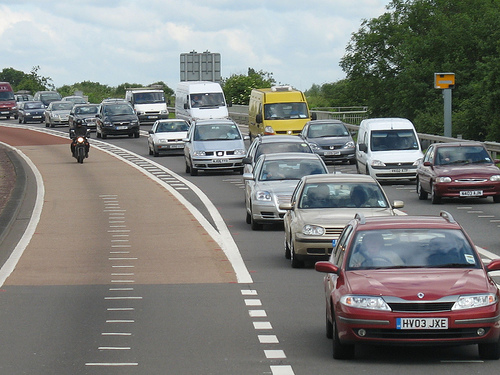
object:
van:
[0, 79, 19, 121]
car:
[43, 101, 69, 129]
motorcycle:
[68, 128, 93, 165]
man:
[69, 118, 91, 141]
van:
[93, 97, 141, 139]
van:
[181, 120, 248, 177]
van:
[248, 86, 311, 146]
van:
[172, 79, 231, 121]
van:
[124, 87, 168, 125]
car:
[311, 209, 498, 360]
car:
[411, 140, 499, 204]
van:
[354, 116, 426, 185]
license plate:
[393, 315, 447, 330]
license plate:
[456, 191, 485, 198]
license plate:
[168, 144, 185, 149]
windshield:
[343, 227, 482, 270]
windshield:
[295, 182, 391, 210]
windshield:
[369, 128, 419, 150]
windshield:
[259, 99, 312, 120]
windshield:
[131, 91, 169, 104]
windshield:
[100, 105, 137, 117]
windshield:
[0, 92, 14, 100]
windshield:
[193, 123, 243, 142]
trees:
[341, 0, 499, 148]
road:
[0, 122, 499, 374]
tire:
[429, 178, 442, 204]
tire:
[330, 318, 353, 362]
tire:
[153, 146, 163, 156]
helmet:
[75, 118, 86, 125]